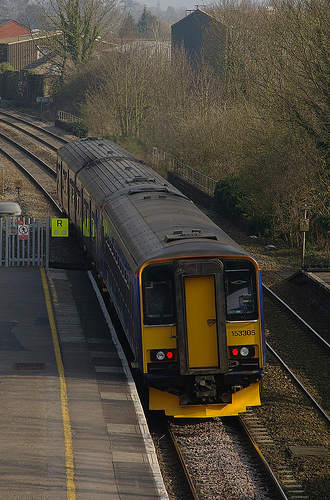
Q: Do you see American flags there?
A: No, there are no American flags.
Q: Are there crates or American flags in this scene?
A: No, there are no American flags or crates.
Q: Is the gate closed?
A: Yes, the gate is closed.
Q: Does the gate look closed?
A: Yes, the gate is closed.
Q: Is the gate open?
A: No, the gate is closed.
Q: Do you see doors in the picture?
A: Yes, there is a door.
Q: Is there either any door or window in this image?
A: Yes, there is a door.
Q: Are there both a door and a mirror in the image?
A: No, there is a door but no mirrors.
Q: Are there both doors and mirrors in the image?
A: No, there is a door but no mirrors.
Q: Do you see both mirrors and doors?
A: No, there is a door but no mirrors.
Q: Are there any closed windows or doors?
A: Yes, there is a closed door.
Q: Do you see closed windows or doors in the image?
A: Yes, there is a closed door.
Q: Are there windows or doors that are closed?
A: Yes, the door is closed.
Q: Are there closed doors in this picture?
A: Yes, there is a closed door.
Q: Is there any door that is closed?
A: Yes, there is a door that is closed.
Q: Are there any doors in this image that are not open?
A: Yes, there is an closed door.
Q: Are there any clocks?
A: No, there are no clocks.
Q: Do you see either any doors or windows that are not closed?
A: No, there is a door but it is closed.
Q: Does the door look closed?
A: Yes, the door is closed.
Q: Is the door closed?
A: Yes, the door is closed.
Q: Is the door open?
A: No, the door is closed.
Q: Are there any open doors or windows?
A: No, there is a door but it is closed.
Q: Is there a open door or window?
A: No, there is a door but it is closed.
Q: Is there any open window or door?
A: No, there is a door but it is closed.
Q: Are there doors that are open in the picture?
A: No, there is a door but it is closed.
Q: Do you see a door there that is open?
A: No, there is a door but it is closed.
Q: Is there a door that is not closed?
A: No, there is a door but it is closed.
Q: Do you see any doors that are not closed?
A: No, there is a door but it is closed.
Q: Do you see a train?
A: Yes, there is a train.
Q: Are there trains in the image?
A: Yes, there is a train.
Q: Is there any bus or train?
A: Yes, there is a train.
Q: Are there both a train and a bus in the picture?
A: No, there is a train but no buses.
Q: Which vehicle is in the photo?
A: The vehicle is a train.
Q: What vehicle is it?
A: The vehicle is a train.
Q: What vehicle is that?
A: That is a train.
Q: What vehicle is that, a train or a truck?
A: That is a train.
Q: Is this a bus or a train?
A: This is a train.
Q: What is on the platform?
A: The train is on the platform.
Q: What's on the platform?
A: The train is on the platform.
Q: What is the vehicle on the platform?
A: The vehicle is a train.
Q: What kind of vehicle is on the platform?
A: The vehicle is a train.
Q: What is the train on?
A: The train is on the platform.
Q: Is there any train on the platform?
A: Yes, there is a train on the platform.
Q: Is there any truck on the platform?
A: No, there is a train on the platform.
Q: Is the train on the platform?
A: Yes, the train is on the platform.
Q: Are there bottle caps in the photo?
A: No, there are no bottle caps.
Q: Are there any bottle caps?
A: No, there are no bottle caps.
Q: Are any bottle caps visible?
A: No, there are no bottle caps.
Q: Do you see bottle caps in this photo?
A: No, there are no bottle caps.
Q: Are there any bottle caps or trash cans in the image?
A: No, there are no bottle caps or trash cans.